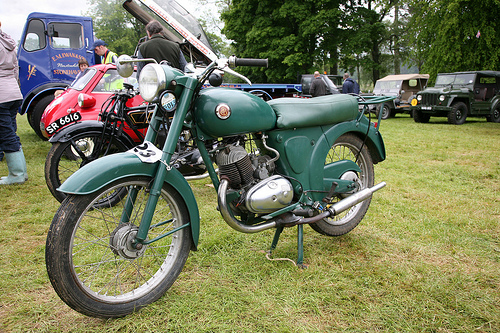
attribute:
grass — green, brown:
[0, 113, 497, 330]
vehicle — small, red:
[34, 48, 156, 165]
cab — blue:
[410, 54, 498, 125]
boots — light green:
[10, 143, 70, 191]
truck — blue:
[6, 11, 316, 118]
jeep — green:
[408, 67, 498, 125]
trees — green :
[78, 1, 498, 86]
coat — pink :
[0, 33, 22, 104]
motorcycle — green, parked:
[58, 62, 383, 286]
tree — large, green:
[216, 3, 334, 69]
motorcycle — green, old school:
[32, 67, 426, 325]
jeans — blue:
[2, 92, 34, 208]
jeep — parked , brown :
[365, 69, 427, 117]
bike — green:
[41, 46, 398, 329]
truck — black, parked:
[412, 69, 497, 124]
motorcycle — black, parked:
[43, 79, 247, 210]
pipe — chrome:
[296, 181, 387, 226]